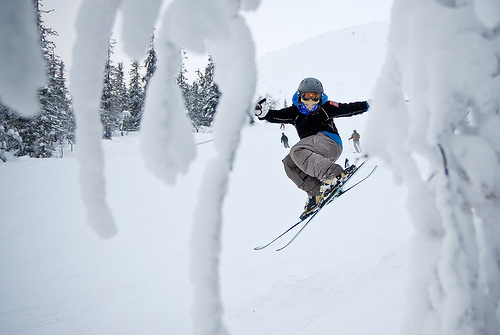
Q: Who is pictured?
A: A snow skier.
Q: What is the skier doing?
A: Jumping.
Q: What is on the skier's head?
A: Helmet.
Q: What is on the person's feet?
A: Skis.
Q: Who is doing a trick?
A: The skier.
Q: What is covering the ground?
A: Snow.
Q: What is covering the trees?
A: Snow.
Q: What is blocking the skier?
A: Branches covered with snow.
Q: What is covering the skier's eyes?
A: Orange goggles.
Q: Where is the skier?
A: On a slope.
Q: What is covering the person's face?
A: Ski mask.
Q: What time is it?
A: Afternoon.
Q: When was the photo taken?
A: During the daytime.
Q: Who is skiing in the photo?
A: Some people.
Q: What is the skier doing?
A: Jumping in the air.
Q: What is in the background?
A: Many trees.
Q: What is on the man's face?
A: Goggles.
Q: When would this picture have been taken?
A: Winter.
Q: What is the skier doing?
A: Performing a jump.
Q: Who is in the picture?
A: A skier.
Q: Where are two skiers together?
A: Behind the front skier.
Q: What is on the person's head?
A: Helmet.